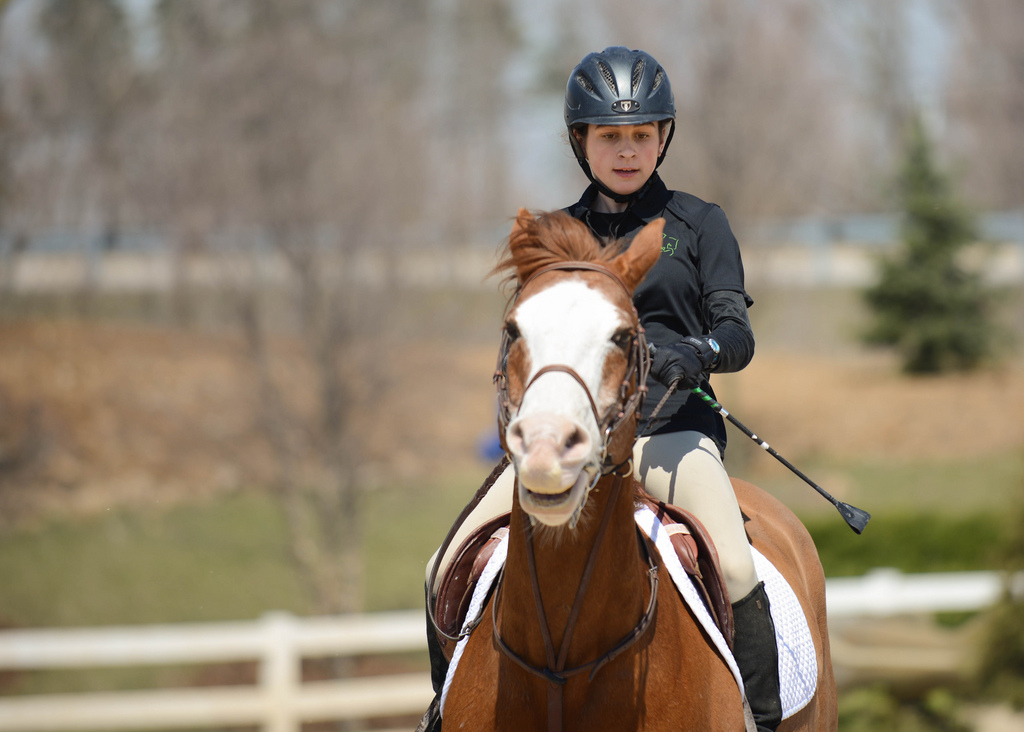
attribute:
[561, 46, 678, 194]
helmet — black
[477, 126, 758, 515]
shirt — black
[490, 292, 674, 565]
face — white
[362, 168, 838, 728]
horse — brown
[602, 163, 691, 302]
ear — big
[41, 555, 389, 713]
fence — white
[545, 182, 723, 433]
shirt — black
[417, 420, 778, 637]
pants — tan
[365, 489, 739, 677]
saddle — brown, leather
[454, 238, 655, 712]
harness — brown leather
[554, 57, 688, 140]
riding helmet — black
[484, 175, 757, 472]
jacket — black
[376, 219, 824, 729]
horse — brown and white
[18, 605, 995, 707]
fence — white, wooden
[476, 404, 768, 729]
pants — tan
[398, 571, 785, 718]
riding boots — black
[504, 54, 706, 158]
helmet — black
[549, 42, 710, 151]
helmet — black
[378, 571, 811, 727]
boots — black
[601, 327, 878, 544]
riding crop — black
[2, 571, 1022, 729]
fence — white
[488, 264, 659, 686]
bridle — brown, leather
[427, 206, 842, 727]
horse — brown and white, white, brown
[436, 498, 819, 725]
blanket — white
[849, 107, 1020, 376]
pine tree — blurry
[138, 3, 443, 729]
tree — bare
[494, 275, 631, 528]
face — white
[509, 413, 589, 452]
nostrils — white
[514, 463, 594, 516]
mouth — white, open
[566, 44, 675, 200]
helmet — black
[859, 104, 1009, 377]
tree — green